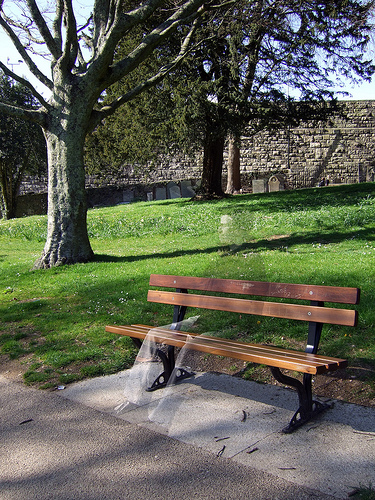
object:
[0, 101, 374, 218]
wall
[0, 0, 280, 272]
tree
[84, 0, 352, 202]
tree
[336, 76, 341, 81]
leaves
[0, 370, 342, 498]
pavement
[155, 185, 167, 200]
gravestones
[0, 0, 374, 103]
sky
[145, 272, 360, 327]
bench back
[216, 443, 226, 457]
debris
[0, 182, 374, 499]
ground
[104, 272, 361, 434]
bench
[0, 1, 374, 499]
park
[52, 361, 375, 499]
slab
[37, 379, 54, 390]
green grass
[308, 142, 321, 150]
stones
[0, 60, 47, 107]
branches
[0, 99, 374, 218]
building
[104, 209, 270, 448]
ghost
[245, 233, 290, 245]
dirt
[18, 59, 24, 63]
street light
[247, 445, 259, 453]
sticks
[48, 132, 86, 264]
trunk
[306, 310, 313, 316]
screw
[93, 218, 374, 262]
shadow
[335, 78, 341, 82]
leaves